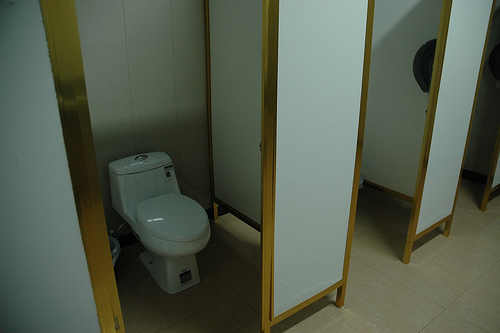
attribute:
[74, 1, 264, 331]
stall — white, door-less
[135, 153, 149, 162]
flush button — silver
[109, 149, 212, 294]
toilet — white, small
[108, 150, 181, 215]
toilet tank — short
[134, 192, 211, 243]
seat — down, plastic, white, closed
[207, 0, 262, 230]
wall — thin, white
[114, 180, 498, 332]
floor — ceramic, tiled, tan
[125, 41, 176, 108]
tile — white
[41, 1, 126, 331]
trim — shiny, brown, gold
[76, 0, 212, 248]
wall — tile, white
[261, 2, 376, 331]
wall — wooden, white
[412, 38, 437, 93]
paper dispenser — black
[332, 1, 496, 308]
stall — white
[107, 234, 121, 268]
bag — white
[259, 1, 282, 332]
trim — gold, brown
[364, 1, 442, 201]
wall — white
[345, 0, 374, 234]
trim — brown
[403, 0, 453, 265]
trim — brown